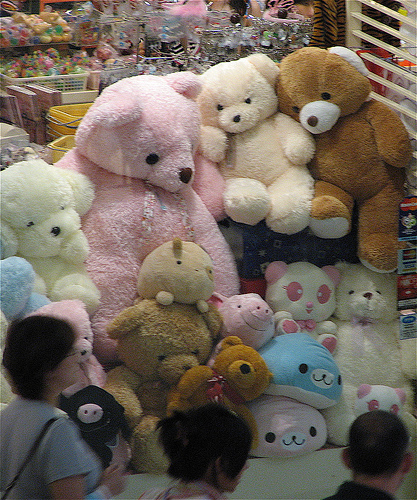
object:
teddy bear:
[103, 298, 222, 475]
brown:
[104, 297, 220, 474]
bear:
[57, 72, 274, 364]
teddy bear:
[36, 299, 132, 478]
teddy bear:
[325, 260, 416, 449]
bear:
[276, 46, 411, 276]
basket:
[48, 134, 75, 165]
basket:
[45, 102, 97, 141]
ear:
[341, 448, 355, 471]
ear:
[403, 449, 413, 475]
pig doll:
[59, 385, 133, 467]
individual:
[320, 409, 414, 499]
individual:
[135, 398, 254, 500]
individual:
[0, 315, 126, 500]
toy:
[249, 393, 327, 458]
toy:
[0, 159, 102, 318]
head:
[340, 409, 414, 489]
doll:
[210, 290, 275, 351]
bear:
[197, 53, 315, 237]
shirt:
[0, 398, 102, 500]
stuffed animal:
[136, 240, 215, 314]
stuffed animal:
[264, 261, 341, 356]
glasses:
[50, 346, 87, 370]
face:
[59, 344, 80, 384]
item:
[64, 16, 101, 42]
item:
[308, 0, 345, 49]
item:
[0, 67, 90, 92]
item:
[229, 14, 242, 24]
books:
[0, 83, 62, 144]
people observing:
[0, 314, 411, 500]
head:
[0, 314, 80, 399]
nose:
[307, 115, 319, 127]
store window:
[0, 0, 417, 499]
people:
[0, 315, 413, 500]